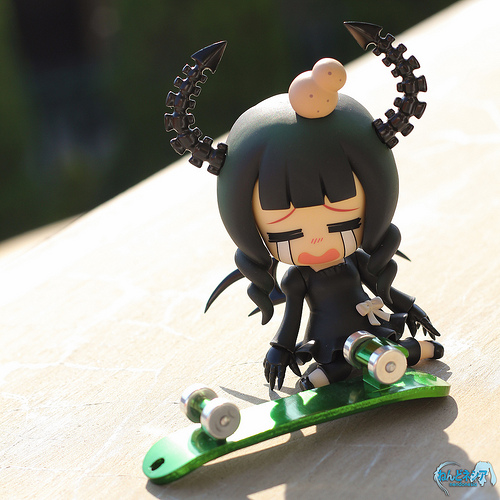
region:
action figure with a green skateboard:
[95, 19, 462, 479]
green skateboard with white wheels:
[136, 321, 453, 490]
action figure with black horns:
[165, 6, 454, 382]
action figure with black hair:
[149, 13, 441, 383]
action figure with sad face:
[136, 23, 451, 392]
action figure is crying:
[135, 19, 447, 398]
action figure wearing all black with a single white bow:
[146, 8, 448, 393]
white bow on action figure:
[348, 293, 393, 326]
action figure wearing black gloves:
[144, 13, 444, 396]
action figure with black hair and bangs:
[165, 17, 452, 396]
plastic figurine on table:
[109, 10, 469, 454]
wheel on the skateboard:
[206, 405, 233, 440]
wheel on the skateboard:
[183, 390, 203, 412]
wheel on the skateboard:
[370, 350, 405, 382]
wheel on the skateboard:
[340, 338, 360, 372]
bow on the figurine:
[355, 304, 387, 330]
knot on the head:
[283, 58, 355, 120]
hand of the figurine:
[243, 331, 299, 386]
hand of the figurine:
[407, 303, 437, 338]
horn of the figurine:
[163, 30, 233, 170]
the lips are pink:
[301, 252, 340, 264]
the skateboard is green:
[258, 409, 318, 426]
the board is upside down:
[145, 414, 299, 458]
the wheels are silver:
[364, 347, 409, 386]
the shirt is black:
[321, 296, 351, 319]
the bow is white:
[351, 297, 391, 325]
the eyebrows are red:
[267, 211, 302, 223]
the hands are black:
[258, 344, 295, 383]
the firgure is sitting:
[249, 309, 455, 371]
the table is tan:
[345, 442, 413, 487]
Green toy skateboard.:
[141, 331, 451, 484]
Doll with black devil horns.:
[164, 20, 443, 390]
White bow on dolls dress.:
[354, 295, 390, 326]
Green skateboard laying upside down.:
[143, 330, 450, 483]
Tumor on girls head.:
[289, 57, 345, 117]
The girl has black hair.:
[218, 92, 398, 324]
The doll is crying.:
[165, 20, 444, 389]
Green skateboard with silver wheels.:
[142, 330, 451, 483]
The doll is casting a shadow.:
[146, 355, 499, 497]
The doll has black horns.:
[163, 19, 427, 178]